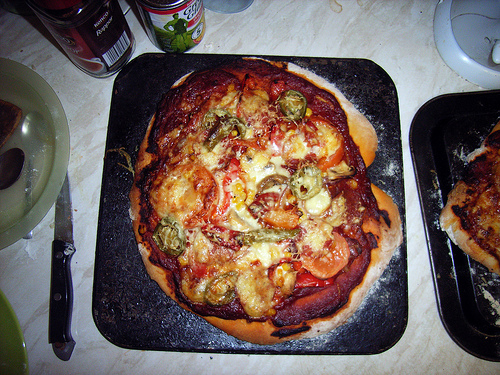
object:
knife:
[49, 169, 77, 361]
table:
[2, 0, 499, 375]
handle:
[46, 243, 75, 362]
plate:
[1, 292, 30, 372]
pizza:
[128, 59, 399, 340]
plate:
[1, 58, 68, 249]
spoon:
[20, 113, 50, 233]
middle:
[197, 108, 320, 279]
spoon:
[0, 148, 27, 192]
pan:
[91, 47, 407, 362]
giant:
[158, 12, 192, 49]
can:
[135, 1, 206, 53]